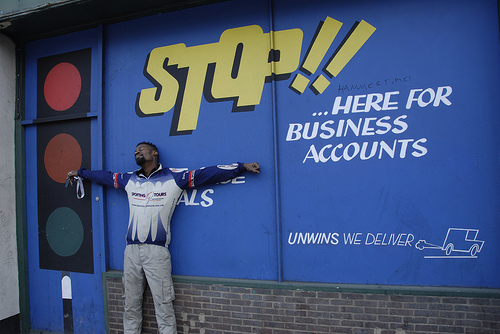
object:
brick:
[242, 305, 286, 316]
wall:
[3, 2, 500, 333]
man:
[66, 140, 260, 333]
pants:
[122, 243, 177, 333]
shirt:
[77, 162, 245, 249]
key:
[65, 171, 86, 199]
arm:
[77, 167, 129, 189]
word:
[134, 16, 376, 137]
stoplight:
[44, 132, 83, 184]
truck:
[415, 228, 486, 259]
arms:
[179, 163, 243, 188]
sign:
[285, 85, 428, 164]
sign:
[288, 232, 415, 247]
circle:
[43, 62, 81, 111]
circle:
[45, 207, 84, 258]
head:
[134, 141, 159, 167]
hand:
[243, 162, 260, 174]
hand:
[68, 170, 78, 176]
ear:
[153, 150, 158, 156]